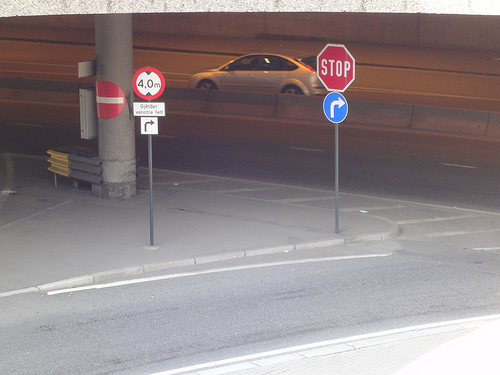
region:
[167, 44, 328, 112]
a silver car on road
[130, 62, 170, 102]
a red and white traffic sign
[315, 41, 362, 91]
a red stop sign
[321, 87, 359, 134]
a blue and white right turn sign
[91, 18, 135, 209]
a large grey concrete pillar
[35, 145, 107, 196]
yellow and grey barricade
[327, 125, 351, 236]
a metal sign post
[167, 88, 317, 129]
grey concrete divider wall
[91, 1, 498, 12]
grey side of overpass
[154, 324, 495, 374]
grey side walk on side of road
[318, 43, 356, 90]
red stop sign on a city street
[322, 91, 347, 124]
blue round turning sign on a city street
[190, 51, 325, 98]
silver small metallic car on a city street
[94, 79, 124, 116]
red sign on a large pole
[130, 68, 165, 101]
round red and white speed limit sign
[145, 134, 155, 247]
long metal pole on a street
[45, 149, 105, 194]
metal divider on a pole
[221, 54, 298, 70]
clear glass window on a car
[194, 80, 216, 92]
small black tire on a car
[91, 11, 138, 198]
large tall pole on a street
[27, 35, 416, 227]
car driving under bridge or underpass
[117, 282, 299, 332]
street is gray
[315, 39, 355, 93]
red and white stop sign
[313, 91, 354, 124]
blue sign with white turning arrow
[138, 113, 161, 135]
black and white sign with arrow pointing right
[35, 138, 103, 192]
restrictive barrier with yellow paint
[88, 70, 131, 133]
circular red sign with one flat white line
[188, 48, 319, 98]
four door small white car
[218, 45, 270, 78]
person driving small white car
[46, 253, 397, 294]
white lines are painted on street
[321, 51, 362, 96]
The sign says stop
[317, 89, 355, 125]
The sign is white and blue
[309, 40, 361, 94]
The sign is red and white and says stop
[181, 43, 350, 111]
There is a silver car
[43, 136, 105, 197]
The guard rail is yellow and grey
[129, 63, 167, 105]
The sign says 4.0m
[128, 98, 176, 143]
The signs are white and black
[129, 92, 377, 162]
The arrows point to the right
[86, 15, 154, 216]
The pole has a red and white sign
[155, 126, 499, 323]
There are white lines on the ground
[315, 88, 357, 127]
blue and white turn sign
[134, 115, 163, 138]
black and white turn sign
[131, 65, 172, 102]
red, white, and black caution sign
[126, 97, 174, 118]
rectangular black and white traffic sign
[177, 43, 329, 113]
black and tan hatchback car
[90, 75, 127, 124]
red and white do not enter sign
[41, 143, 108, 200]
grey and yellow guard rail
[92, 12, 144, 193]
grey concrete pillar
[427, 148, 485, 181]
white paint lane line